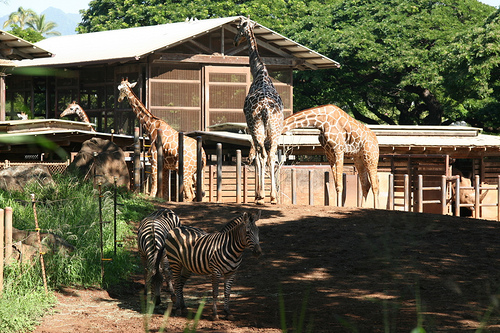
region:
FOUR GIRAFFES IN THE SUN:
[51, 16, 406, 214]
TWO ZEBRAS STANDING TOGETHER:
[121, 198, 291, 324]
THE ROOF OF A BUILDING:
[24, 11, 346, 71]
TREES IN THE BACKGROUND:
[304, 3, 498, 118]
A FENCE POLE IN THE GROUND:
[15, 186, 72, 300]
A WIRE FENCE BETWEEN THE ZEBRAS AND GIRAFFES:
[20, 191, 412, 306]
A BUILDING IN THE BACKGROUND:
[13, 14, 345, 146]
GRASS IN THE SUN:
[6, 178, 134, 318]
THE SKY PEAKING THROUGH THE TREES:
[7, 4, 101, 36]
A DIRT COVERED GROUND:
[63, 284, 213, 331]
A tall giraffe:
[226, 5, 286, 205]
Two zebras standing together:
[130, 195, 275, 310]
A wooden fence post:
[285, 165, 300, 202]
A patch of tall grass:
[35, 180, 95, 226]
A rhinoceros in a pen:
[435, 155, 490, 210]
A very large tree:
[322, 0, 497, 125]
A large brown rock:
[65, 130, 131, 195]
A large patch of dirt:
[280, 205, 490, 295]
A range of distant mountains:
[30, 1, 85, 26]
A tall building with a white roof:
[37, 20, 312, 116]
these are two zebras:
[132, 202, 263, 317]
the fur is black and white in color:
[151, 237, 216, 258]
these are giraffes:
[111, 17, 381, 202]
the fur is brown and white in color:
[161, 128, 177, 160]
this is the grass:
[76, 213, 98, 269]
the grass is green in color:
[73, 203, 97, 270]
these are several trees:
[348, 5, 457, 118]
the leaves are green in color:
[363, 12, 471, 105]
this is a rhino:
[444, 161, 486, 211]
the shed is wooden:
[398, 132, 484, 151]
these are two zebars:
[137, 212, 266, 324]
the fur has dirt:
[166, 233, 202, 259]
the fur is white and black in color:
[160, 232, 203, 257]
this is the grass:
[45, 200, 84, 217]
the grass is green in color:
[58, 195, 93, 220]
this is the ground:
[286, 222, 425, 309]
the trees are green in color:
[377, 63, 464, 85]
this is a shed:
[386, 128, 498, 215]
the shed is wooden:
[393, 128, 430, 145]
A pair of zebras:
[138, 203, 274, 324]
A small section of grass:
[6, 190, 126, 299]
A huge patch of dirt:
[263, 201, 499, 331]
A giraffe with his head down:
[246, 107, 386, 202]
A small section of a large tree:
[360, 6, 494, 125]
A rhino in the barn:
[449, 158, 489, 218]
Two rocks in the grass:
[3, 132, 133, 211]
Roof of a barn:
[39, 10, 230, 65]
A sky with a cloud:
[41, 2, 74, 34]